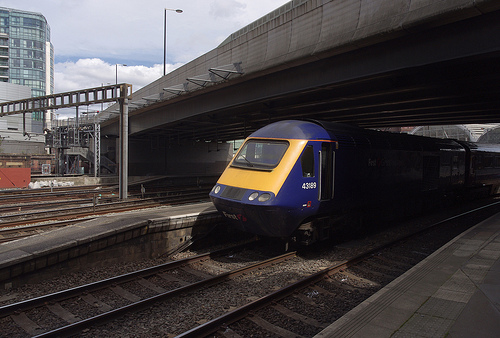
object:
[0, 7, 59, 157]
building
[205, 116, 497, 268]
train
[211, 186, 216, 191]
headlights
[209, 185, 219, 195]
headlights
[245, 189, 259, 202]
headlights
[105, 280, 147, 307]
wood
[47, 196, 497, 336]
ballas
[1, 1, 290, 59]
clouds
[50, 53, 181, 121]
clouds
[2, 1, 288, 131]
sky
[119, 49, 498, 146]
underside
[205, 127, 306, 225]
front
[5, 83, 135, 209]
frame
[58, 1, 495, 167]
bridge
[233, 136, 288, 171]
windshield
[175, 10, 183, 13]
light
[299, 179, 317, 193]
number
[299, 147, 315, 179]
window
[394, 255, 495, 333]
platform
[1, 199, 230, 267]
walkway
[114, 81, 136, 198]
post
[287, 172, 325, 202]
background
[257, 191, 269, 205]
headlights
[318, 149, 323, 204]
handle bars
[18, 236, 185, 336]
tracks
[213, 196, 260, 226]
part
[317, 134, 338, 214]
door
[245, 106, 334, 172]
top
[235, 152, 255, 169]
windshield wiper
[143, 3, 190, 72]
streetlight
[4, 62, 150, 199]
tracks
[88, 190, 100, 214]
metal post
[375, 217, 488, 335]
platform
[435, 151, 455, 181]
winshield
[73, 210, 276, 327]
track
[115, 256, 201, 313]
track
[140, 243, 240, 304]
stones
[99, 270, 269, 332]
ground